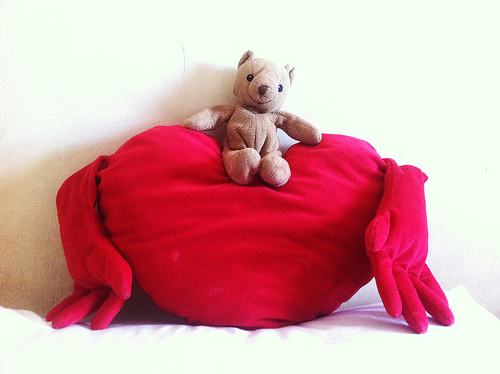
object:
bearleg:
[256, 151, 291, 189]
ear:
[236, 49, 258, 68]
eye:
[244, 72, 255, 82]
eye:
[277, 82, 284, 93]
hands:
[361, 157, 455, 334]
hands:
[45, 152, 135, 332]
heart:
[44, 124, 454, 337]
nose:
[257, 83, 266, 97]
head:
[231, 50, 296, 113]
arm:
[180, 103, 240, 131]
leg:
[221, 147, 261, 186]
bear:
[183, 50, 322, 188]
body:
[180, 103, 324, 189]